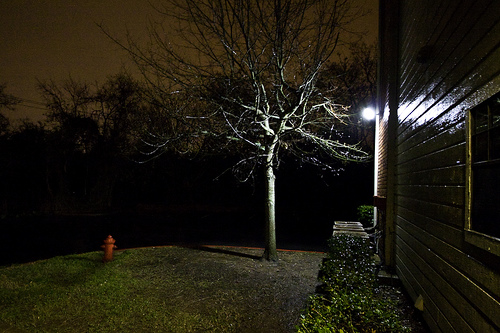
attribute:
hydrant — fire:
[94, 234, 116, 265]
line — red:
[287, 237, 328, 267]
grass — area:
[1, 243, 303, 329]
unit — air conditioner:
[333, 227, 368, 240]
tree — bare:
[111, 17, 371, 260]